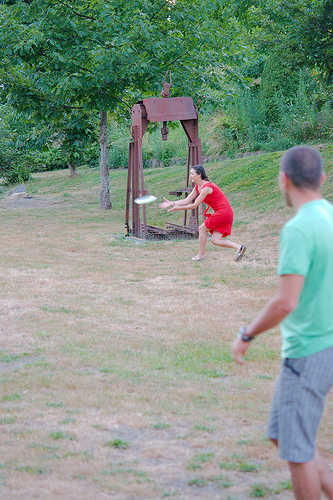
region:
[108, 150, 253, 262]
Women trying to catch a frisbee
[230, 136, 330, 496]
Man standing with back towards camera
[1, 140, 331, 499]
Grass that looks like it's dying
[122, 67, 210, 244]
Rusted metal structure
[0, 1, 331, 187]
Trees and other plants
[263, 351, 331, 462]
Blue stripped shorts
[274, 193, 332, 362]
Green T-shirt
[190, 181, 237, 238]
Red Dress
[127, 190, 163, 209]
White flying frisbee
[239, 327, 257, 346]
Watch being worn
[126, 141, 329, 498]
A man standing and playing frisbee in a green t shirt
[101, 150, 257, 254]
A woman in a red dress moving to catch a frisbee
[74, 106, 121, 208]
A gray and brown trunk of a tree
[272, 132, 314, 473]
A man wearing gray striped shorts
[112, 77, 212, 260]
A tall brown structure standing in a field of grass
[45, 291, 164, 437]
A field of green grass and many patches of brown dirt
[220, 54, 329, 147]
Thick green shrubbery standing before a forest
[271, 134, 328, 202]
Head of a man with dark hair cut very short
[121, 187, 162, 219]
A white frisbee flying through the air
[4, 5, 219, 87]
Thick green leaves of a tree covering it's branches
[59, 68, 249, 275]
a lady is playing with a frisbee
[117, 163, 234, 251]
the frisbee is about to be caught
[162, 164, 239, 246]
the lady has a red dress on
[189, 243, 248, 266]
the girl is wearing flats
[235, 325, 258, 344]
the man is wearing a watch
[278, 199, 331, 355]
the man is wearing a green t-shirt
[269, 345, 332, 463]
pinstripe shorts are on the man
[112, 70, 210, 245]
an iron contraption is behind the lady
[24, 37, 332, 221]
bushes and trees are behind the park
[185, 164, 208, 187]
the girl has black hair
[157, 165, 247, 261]
a woman in a red dress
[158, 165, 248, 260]
a woman about to catch a frisbee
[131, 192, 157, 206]
a white frisbee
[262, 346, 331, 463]
a pair of striped shorts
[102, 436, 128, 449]
a patch of green grass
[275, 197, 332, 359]
a light green t-shirt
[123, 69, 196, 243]
a metal pulley system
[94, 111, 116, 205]
a narrow tree trunk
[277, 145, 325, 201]
a man's head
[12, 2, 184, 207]
a leafy green tree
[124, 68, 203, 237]
a small wooden gazebo in a park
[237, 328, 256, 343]
a man wearing a watch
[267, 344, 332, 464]
man wearing long white and blue stripe shorts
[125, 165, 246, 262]
woman about to catch a frisbee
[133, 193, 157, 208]
a frisbee flying in the air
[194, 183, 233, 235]
woman wearing a red dress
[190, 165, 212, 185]
woman with brown braided hair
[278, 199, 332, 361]
man wearing a light green shirt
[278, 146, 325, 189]
man with a buzz cut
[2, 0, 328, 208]
green trees and bushes in a park